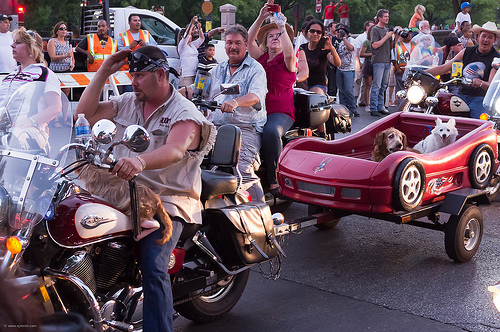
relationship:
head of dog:
[370, 126, 412, 145] [373, 120, 423, 156]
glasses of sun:
[123, 48, 161, 71] [489, 2, 493, 21]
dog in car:
[373, 120, 423, 156] [287, 105, 498, 179]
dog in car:
[419, 112, 473, 154] [287, 105, 498, 179]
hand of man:
[218, 93, 245, 118] [203, 18, 268, 185]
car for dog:
[287, 105, 498, 179] [373, 120, 423, 156]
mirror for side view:
[122, 131, 168, 150] [59, 14, 67, 18]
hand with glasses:
[107, 47, 139, 73] [123, 48, 161, 71]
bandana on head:
[123, 64, 169, 77] [370, 126, 412, 145]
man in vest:
[94, 6, 122, 75] [86, 22, 124, 72]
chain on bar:
[264, 248, 297, 269] [282, 208, 336, 241]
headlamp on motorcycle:
[4, 176, 51, 262] [3, 89, 264, 305]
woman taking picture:
[262, 11, 315, 131] [247, 4, 307, 54]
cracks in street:
[295, 263, 366, 311] [379, 255, 494, 324]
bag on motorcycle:
[211, 186, 284, 270] [3, 89, 264, 305]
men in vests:
[84, 13, 171, 63] [81, 29, 150, 52]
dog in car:
[368, 126, 420, 161] [287, 105, 498, 179]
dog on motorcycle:
[76, 144, 174, 244] [3, 89, 264, 305]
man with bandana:
[203, 18, 268, 185] [123, 64, 169, 77]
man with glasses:
[92, 51, 190, 300] [123, 48, 161, 71]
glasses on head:
[123, 48, 161, 71] [123, 38, 178, 118]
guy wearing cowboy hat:
[458, 4, 498, 111] [469, 13, 498, 51]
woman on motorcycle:
[262, 11, 315, 131] [3, 89, 264, 305]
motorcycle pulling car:
[3, 89, 264, 305] [287, 105, 498, 179]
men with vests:
[84, 13, 171, 63] [81, 29, 150, 52]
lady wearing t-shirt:
[289, 17, 333, 80] [302, 42, 327, 90]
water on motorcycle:
[67, 113, 106, 159] [3, 89, 264, 305]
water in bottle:
[67, 113, 106, 159] [80, 111, 94, 119]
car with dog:
[287, 105, 498, 179] [368, 126, 420, 161]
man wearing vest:
[203, 18, 268, 185] [86, 22, 124, 72]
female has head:
[13, 23, 48, 67] [10, 25, 42, 54]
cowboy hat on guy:
[469, 13, 498, 51] [458, 4, 498, 111]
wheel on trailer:
[448, 198, 490, 255] [364, 194, 498, 257]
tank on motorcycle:
[62, 192, 127, 245] [3, 89, 264, 305]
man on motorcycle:
[92, 51, 190, 300] [3, 89, 264, 305]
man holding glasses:
[92, 51, 190, 300] [123, 48, 161, 71]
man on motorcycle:
[203, 18, 268, 185] [174, 90, 325, 168]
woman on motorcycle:
[262, 11, 315, 131] [174, 90, 325, 168]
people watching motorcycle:
[341, 4, 446, 90] [3, 89, 264, 305]